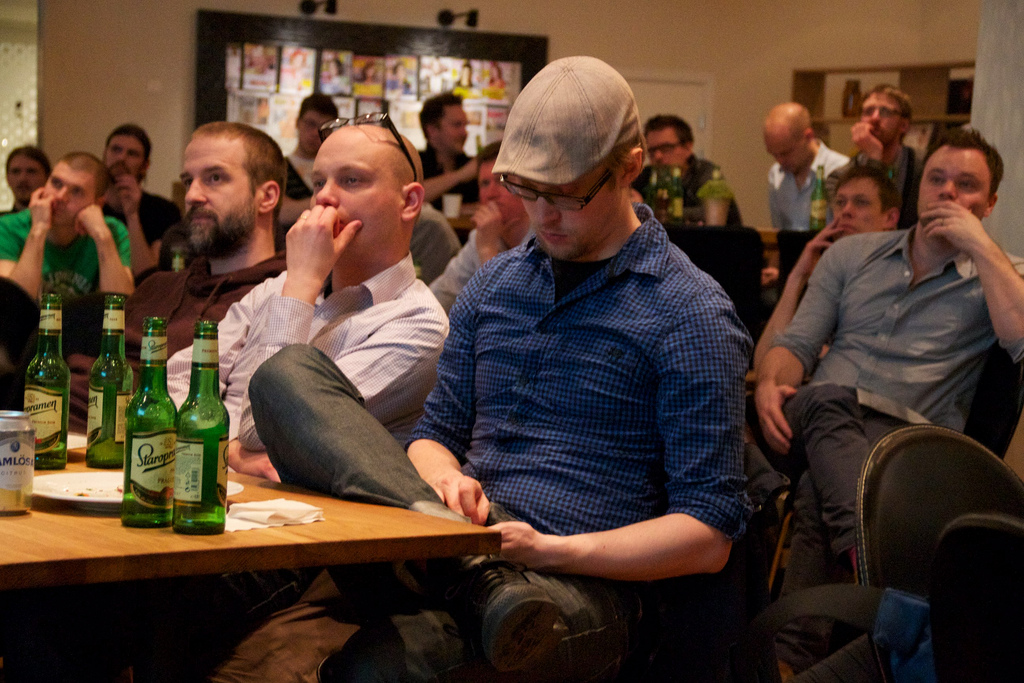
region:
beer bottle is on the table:
[173, 321, 232, 536]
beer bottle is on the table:
[125, 308, 176, 521]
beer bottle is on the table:
[90, 288, 128, 479]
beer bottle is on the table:
[21, 280, 61, 454]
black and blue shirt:
[416, 210, 736, 527]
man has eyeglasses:
[475, 157, 628, 211]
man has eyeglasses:
[308, 109, 430, 183]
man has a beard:
[169, 194, 258, 255]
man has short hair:
[180, 115, 285, 192]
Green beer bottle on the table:
[169, 311, 233, 520]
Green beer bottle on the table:
[130, 320, 170, 533]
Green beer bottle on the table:
[76, 282, 133, 475]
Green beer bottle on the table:
[13, 285, 83, 445]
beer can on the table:
[1, 396, 50, 507]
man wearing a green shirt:
[12, 206, 124, 283]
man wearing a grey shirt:
[781, 231, 971, 425]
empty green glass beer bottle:
[171, 320, 228, 527]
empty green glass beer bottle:
[117, 313, 176, 528]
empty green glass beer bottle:
[87, 293, 142, 470]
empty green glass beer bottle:
[22, 291, 71, 470]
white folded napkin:
[223, 492, 323, 535]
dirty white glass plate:
[22, 470, 247, 506]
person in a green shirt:
[3, 146, 133, 296]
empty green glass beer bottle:
[805, 162, 829, 227]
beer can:
[0, 410, 33, 509]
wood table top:
[2, 423, 502, 591]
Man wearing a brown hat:
[470, 45, 636, 197]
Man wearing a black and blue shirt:
[414, 212, 756, 542]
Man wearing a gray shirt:
[783, 217, 993, 429]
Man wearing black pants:
[236, 328, 623, 677]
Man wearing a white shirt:
[187, 249, 435, 437]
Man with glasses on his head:
[300, 97, 427, 189]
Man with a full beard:
[158, 176, 277, 259]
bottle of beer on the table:
[119, 312, 186, 525]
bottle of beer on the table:
[73, 284, 144, 447]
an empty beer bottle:
[171, 318, 225, 531]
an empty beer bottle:
[117, 314, 174, 526]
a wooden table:
[0, 432, 500, 591]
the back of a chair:
[861, 423, 1020, 679]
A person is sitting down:
[256, 77, 779, 670]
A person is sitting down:
[177, 134, 443, 461]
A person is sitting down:
[68, 106, 300, 385]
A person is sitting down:
[22, 141, 156, 328]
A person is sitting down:
[57, 118, 195, 264]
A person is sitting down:
[6, 152, 48, 214]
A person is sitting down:
[268, 100, 316, 177]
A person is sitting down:
[379, 98, 472, 207]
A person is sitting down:
[408, 131, 546, 313]